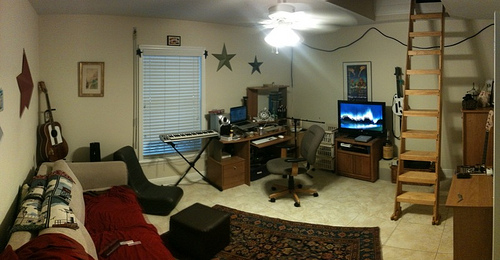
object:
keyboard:
[158, 129, 217, 140]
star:
[210, 42, 237, 73]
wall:
[37, 16, 288, 182]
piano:
[156, 125, 222, 193]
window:
[131, 53, 208, 160]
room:
[0, 0, 499, 259]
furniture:
[0, 159, 178, 259]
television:
[333, 97, 385, 137]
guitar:
[31, 81, 70, 161]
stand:
[34, 79, 68, 161]